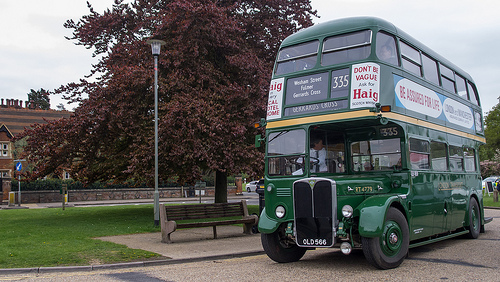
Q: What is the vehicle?
A: Double Decker bus.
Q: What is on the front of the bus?
A: Windshield.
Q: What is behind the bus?
A: Tree.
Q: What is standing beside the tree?
A: Light.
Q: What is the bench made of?
A: Wood.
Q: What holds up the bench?
A: Concrete.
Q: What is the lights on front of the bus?
A: Headlights.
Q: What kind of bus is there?
A: Double decker.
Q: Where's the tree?
A: Right of bus.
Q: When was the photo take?
A: Daytime.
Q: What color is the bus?
A: Green.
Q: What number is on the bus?
A: 335.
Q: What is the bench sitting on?
A: Concrete.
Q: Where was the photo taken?
A: At a bus stop.